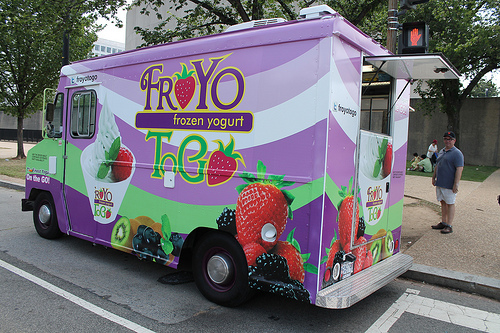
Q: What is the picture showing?
A: It is showing a road.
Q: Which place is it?
A: It is a road.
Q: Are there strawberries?
A: Yes, there is a strawberry.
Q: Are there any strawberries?
A: Yes, there is a strawberry.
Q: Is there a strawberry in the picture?
A: Yes, there is a strawberry.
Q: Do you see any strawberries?
A: Yes, there is a strawberry.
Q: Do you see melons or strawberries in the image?
A: Yes, there is a strawberry.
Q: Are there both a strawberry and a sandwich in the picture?
A: No, there is a strawberry but no sandwiches.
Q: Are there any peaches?
A: No, there are no peaches.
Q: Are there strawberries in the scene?
A: Yes, there are strawberries.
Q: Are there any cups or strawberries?
A: Yes, there are strawberries.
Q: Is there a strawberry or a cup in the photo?
A: Yes, there are strawberries.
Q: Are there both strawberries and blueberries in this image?
A: No, there are strawberries but no blueberries.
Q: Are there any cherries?
A: No, there are no cherries.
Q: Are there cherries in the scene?
A: No, there are no cherries.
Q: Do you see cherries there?
A: No, there are no cherries.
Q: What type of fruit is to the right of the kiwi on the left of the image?
A: The fruits are strawberries.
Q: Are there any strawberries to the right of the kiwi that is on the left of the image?
A: Yes, there are strawberries to the right of the kiwi.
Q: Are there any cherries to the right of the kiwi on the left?
A: No, there are strawberries to the right of the kiwi.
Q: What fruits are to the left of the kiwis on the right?
A: The fruits are strawberries.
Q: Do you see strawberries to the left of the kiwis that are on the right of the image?
A: Yes, there are strawberries to the left of the kiwis.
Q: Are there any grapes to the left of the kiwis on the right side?
A: No, there are strawberries to the left of the kiwis.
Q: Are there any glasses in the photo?
A: No, there are no glasses.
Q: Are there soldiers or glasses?
A: No, there are no glasses or soldiers.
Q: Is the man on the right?
A: Yes, the man is on the right of the image.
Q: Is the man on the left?
A: No, the man is on the right of the image.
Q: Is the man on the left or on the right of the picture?
A: The man is on the right of the image.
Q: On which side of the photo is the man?
A: The man is on the right of the image.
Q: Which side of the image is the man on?
A: The man is on the right of the image.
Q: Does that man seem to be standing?
A: Yes, the man is standing.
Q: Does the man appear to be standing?
A: Yes, the man is standing.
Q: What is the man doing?
A: The man is standing.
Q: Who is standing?
A: The man is standing.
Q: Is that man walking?
A: No, the man is standing.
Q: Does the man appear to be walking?
A: No, the man is standing.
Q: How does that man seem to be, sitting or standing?
A: The man is standing.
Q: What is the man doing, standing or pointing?
A: The man is standing.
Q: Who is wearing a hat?
A: The man is wearing a hat.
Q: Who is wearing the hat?
A: The man is wearing a hat.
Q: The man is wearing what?
A: The man is wearing a hat.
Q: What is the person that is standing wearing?
A: The man is wearing a hat.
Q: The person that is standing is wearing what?
A: The man is wearing a hat.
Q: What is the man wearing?
A: The man is wearing a hat.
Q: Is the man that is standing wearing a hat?
A: Yes, the man is wearing a hat.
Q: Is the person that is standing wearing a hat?
A: Yes, the man is wearing a hat.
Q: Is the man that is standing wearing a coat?
A: No, the man is wearing a hat.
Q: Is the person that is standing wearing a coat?
A: No, the man is wearing a hat.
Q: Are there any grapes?
A: No, there are no grapes.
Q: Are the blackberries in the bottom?
A: Yes, the blackberries are in the bottom of the image.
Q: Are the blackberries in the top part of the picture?
A: No, the blackberries are in the bottom of the image.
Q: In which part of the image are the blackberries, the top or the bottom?
A: The blackberries are in the bottom of the image.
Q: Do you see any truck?
A: Yes, there is a truck.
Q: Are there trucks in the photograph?
A: Yes, there is a truck.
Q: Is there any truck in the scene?
A: Yes, there is a truck.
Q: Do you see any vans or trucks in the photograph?
A: Yes, there is a truck.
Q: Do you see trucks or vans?
A: Yes, there is a truck.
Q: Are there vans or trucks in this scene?
A: Yes, there is a truck.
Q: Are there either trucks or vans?
A: Yes, there is a truck.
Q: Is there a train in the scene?
A: No, there are no trains.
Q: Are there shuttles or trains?
A: No, there are no trains or shuttles.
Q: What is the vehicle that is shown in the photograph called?
A: The vehicle is a truck.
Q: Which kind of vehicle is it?
A: The vehicle is a truck.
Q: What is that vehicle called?
A: This is a truck.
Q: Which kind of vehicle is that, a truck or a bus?
A: This is a truck.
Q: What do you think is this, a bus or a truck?
A: This is a truck.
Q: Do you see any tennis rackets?
A: No, there are no tennis rackets.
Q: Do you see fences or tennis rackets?
A: No, there are no tennis rackets or fences.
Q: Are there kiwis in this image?
A: Yes, there is a kiwi.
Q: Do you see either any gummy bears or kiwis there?
A: Yes, there is a kiwi.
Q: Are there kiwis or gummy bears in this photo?
A: Yes, there is a kiwi.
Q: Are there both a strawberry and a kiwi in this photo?
A: Yes, there are both a kiwi and a strawberry.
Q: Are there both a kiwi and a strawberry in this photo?
A: Yes, there are both a kiwi and a strawberry.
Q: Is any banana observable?
A: No, there are no bananas.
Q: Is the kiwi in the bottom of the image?
A: Yes, the kiwi is in the bottom of the image.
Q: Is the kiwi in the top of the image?
A: No, the kiwi is in the bottom of the image.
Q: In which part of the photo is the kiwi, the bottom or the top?
A: The kiwi is in the bottom of the image.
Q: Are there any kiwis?
A: Yes, there are kiwis.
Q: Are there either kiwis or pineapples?
A: Yes, there are kiwis.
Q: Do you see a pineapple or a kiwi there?
A: Yes, there are kiwis.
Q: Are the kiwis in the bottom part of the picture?
A: Yes, the kiwis are in the bottom of the image.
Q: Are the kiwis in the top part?
A: No, the kiwis are in the bottom of the image.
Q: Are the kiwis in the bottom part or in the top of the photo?
A: The kiwis are in the bottom of the image.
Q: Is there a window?
A: Yes, there is a window.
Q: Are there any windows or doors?
A: Yes, there is a window.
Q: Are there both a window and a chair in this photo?
A: No, there is a window but no chairs.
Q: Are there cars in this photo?
A: No, there are no cars.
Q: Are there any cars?
A: No, there are no cars.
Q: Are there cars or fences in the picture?
A: No, there are no cars or fences.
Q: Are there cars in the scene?
A: No, there are no cars.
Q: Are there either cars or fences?
A: No, there are no cars or fences.